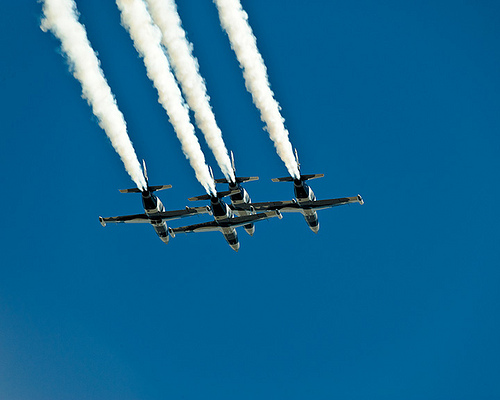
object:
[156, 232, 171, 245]
nose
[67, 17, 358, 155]
tail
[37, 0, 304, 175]
smoke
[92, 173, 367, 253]
jets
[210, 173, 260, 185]
jet tail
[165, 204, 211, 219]
wing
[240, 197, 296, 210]
wing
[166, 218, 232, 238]
wing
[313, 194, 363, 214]
wing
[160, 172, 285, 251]
airplane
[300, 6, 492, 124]
sky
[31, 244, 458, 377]
sky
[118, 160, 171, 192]
tail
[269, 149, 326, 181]
tail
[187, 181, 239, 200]
tail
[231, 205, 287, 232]
wing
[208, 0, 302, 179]
contrail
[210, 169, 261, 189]
tail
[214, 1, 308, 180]
white smoke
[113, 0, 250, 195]
white smoke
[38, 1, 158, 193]
white smoke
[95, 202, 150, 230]
wings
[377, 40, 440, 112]
ground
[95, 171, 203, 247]
airplanes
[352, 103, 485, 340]
sky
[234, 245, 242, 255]
nose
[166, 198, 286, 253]
jet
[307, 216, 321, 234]
nose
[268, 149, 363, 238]
airplanes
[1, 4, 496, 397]
sky